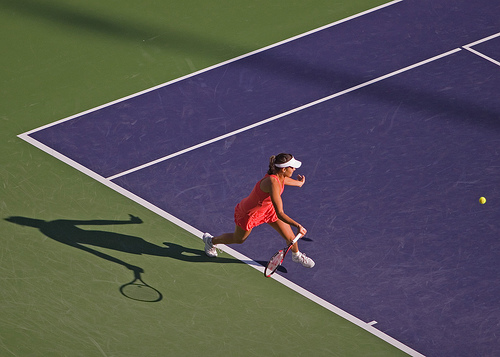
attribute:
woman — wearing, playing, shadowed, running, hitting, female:
[181, 141, 333, 287]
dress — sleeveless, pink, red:
[231, 172, 291, 235]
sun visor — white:
[272, 152, 311, 170]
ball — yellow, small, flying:
[475, 194, 488, 206]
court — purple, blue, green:
[4, 3, 494, 354]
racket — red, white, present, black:
[253, 228, 309, 280]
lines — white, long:
[49, 53, 295, 232]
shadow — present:
[21, 2, 500, 137]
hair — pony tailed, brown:
[267, 147, 292, 173]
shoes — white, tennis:
[208, 237, 317, 273]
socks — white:
[209, 232, 308, 259]